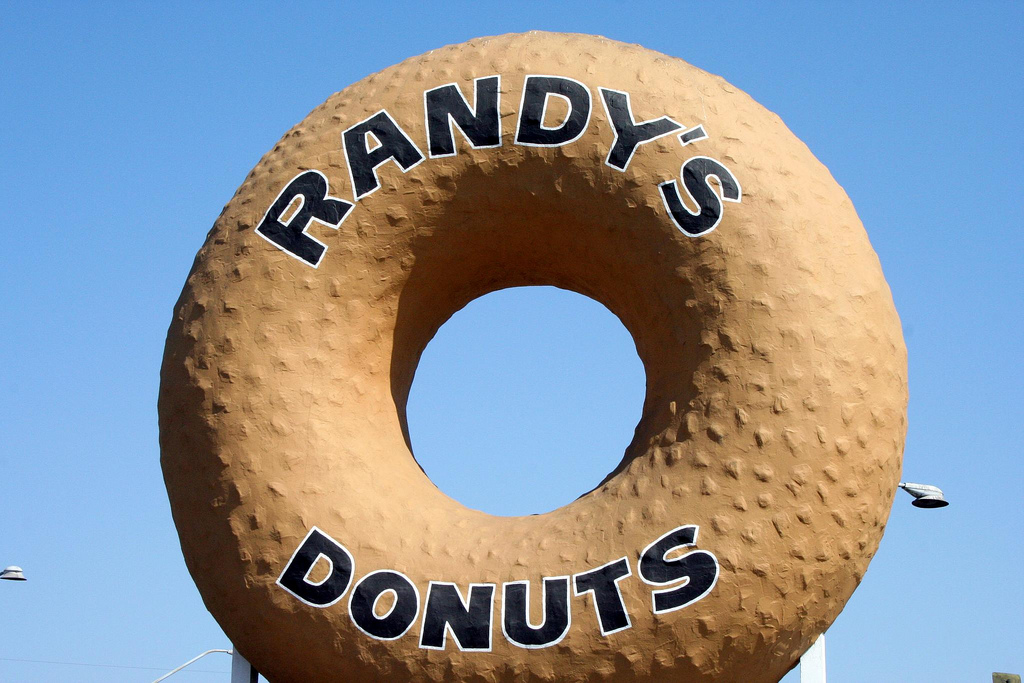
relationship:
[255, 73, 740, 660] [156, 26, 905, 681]
letters on donut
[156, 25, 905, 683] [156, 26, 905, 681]
donut shaped like a donut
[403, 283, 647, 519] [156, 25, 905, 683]
sky in middle of donut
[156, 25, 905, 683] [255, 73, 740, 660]
donut says letters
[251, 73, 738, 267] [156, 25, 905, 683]
randy's on donut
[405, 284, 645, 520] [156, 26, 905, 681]
donut hole of donut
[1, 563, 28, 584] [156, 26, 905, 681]
street light near donut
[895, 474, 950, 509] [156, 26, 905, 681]
street light near donut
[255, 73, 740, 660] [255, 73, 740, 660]
letters around letters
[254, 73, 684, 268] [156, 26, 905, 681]
randy on donut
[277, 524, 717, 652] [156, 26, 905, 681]
donuts on donut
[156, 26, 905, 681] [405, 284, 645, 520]
donut has a donut hole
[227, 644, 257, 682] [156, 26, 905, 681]
pole behind donut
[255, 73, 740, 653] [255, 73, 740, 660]
letters have letters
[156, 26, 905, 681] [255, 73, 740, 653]
donut has letters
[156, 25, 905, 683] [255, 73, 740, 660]
donut for letters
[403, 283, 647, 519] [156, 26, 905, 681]
sky behind donut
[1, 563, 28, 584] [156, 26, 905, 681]
street light behind donut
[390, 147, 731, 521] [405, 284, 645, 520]
shadow around donut hole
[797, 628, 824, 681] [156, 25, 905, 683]
post holding donut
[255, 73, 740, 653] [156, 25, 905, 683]
letters on donut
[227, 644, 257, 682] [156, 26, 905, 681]
pole holding up donut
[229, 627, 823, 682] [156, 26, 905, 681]
supports holding up donut